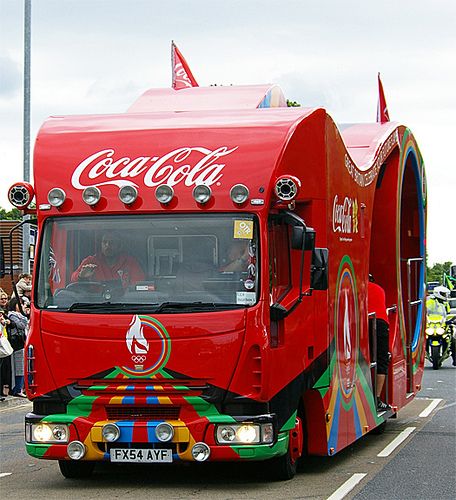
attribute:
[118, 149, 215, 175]
lettering — white, black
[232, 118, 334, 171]
bus — red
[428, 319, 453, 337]
motorcycle — yellow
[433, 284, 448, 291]
helmet — white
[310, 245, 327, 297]
mirror — large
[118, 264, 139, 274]
jacket — red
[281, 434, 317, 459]
wheel — part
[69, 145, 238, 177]
coca cola — sponsor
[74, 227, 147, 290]
driver — driving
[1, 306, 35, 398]
crowd — watching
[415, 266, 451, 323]
man — driving